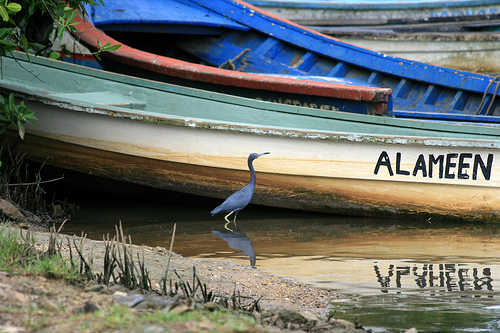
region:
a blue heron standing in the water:
[203, 146, 275, 229]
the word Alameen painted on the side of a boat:
[369, 138, 497, 185]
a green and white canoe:
[0, 45, 499, 218]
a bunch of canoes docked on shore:
[1, 1, 498, 219]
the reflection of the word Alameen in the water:
[366, 253, 498, 301]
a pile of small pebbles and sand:
[224, 275, 343, 312]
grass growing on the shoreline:
[1, 218, 242, 305]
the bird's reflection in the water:
[212, 223, 262, 268]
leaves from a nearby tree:
[0, 0, 130, 140]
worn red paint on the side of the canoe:
[176, 63, 313, 92]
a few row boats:
[24, 3, 496, 229]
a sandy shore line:
[109, 228, 331, 323]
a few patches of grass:
[86, 285, 240, 331]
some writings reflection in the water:
[365, 253, 497, 299]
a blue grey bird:
[208, 150, 273, 223]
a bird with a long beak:
[244, 150, 271, 160]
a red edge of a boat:
[72, 17, 393, 108]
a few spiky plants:
[40, 215, 265, 315]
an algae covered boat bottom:
[39, 138, 376, 220]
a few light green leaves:
[0, 3, 93, 60]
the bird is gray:
[197, 121, 300, 236]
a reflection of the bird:
[220, 230, 267, 272]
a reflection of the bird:
[207, 209, 272, 268]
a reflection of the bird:
[170, 193, 289, 284]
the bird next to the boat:
[210, 151, 270, 223]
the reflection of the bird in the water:
[208, 222, 260, 267]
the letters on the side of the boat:
[373, 148, 494, 180]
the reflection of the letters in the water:
[373, 261, 493, 292]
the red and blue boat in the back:
[61, 0, 498, 123]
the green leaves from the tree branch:
[1, 0, 118, 137]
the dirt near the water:
[4, 218, 340, 317]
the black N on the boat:
[473, 153, 493, 179]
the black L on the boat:
[395, 151, 410, 175]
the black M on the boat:
[427, 153, 444, 178]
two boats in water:
[5, 1, 496, 217]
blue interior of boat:
[96, 2, 493, 105]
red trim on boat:
[110, 41, 379, 101]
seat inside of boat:
[55, 87, 148, 114]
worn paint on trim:
[183, 118, 455, 148]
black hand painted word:
[372, 149, 494, 181]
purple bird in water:
[213, 148, 272, 233]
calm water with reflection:
[120, 219, 497, 326]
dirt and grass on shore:
[5, 226, 321, 331]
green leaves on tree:
[5, 3, 119, 132]